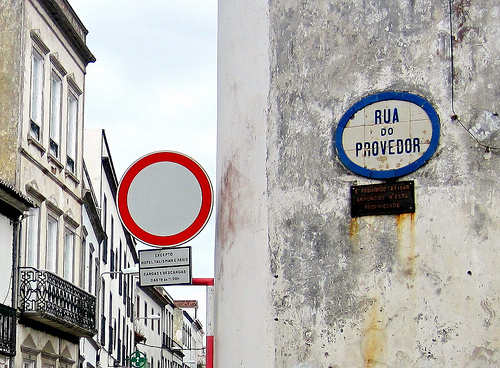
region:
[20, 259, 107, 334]
the balcony is empty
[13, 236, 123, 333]
the balcony is empty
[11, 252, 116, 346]
the balcony is empty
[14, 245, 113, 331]
the balcony is empty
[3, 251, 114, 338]
the balcony is empty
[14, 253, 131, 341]
the balcony is empty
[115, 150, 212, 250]
white circle lines in red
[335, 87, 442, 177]
blue and white tile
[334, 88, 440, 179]
white and blue tile sign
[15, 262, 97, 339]
black metal balcony fence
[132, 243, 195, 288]
rectangular black and white sign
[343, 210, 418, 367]
orange rust stains on cement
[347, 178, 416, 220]
black metal sign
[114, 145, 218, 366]
two signs on a sign pole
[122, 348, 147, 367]
green circle with green cross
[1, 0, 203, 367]
row of white buildings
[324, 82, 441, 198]
a sign on the wall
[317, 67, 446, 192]
a sign on the wall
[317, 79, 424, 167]
a sign on the wall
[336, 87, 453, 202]
a sign on the wall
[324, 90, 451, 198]
a sign on the wall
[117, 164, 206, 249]
red and white sign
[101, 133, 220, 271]
red and white sign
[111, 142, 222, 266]
red and white sign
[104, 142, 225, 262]
red and white sign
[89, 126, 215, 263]
red and white sign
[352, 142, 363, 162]
a letter written in blue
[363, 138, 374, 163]
a letter written in blue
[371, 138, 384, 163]
a letter written in blue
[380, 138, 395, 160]
a letter written in blue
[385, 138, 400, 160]
a letter written in blue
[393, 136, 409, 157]
a letter written in blue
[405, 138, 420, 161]
a letter written in blue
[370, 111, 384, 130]
a letter written in blue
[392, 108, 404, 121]
a letter written in blue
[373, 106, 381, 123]
a letter is written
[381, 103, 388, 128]
a letter is written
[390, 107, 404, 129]
a letter is written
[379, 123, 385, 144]
a letter is written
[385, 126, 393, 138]
a letter is written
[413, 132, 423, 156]
a letter is written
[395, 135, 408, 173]
a letter is written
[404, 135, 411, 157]
a letter is written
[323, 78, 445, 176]
the blue circular sign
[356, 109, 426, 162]
The words in the blue sign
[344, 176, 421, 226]
The black sign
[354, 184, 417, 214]
The black sign has gold words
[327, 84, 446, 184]
a blue and white street sign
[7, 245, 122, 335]
a wire patio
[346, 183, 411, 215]
black plaque on the wall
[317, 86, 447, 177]
blue and white plaque on the wall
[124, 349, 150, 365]
green and white sign on building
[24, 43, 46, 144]
window on the building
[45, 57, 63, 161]
window on the building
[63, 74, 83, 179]
window on the building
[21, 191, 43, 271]
window on the building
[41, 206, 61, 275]
window on the building